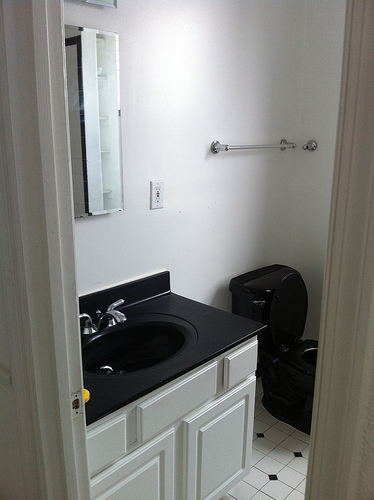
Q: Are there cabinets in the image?
A: Yes, there is a cabinet.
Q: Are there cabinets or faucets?
A: Yes, there is a cabinet.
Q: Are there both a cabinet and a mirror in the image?
A: Yes, there are both a cabinet and a mirror.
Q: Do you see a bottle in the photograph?
A: No, there are no bottles.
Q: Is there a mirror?
A: Yes, there is a mirror.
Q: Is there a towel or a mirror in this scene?
A: Yes, there is a mirror.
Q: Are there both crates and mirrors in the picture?
A: No, there is a mirror but no crates.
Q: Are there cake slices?
A: No, there are no cake slices.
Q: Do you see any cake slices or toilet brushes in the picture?
A: No, there are no cake slices or toilet brushes.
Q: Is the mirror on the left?
A: Yes, the mirror is on the left of the image.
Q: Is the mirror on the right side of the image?
A: No, the mirror is on the left of the image.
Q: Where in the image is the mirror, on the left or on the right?
A: The mirror is on the left of the image.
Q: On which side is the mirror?
A: The mirror is on the left of the image.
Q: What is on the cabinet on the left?
A: The mirror is on the cabinet.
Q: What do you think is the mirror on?
A: The mirror is on the cabinet.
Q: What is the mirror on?
A: The mirror is on the cabinet.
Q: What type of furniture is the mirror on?
A: The mirror is on the cabinet.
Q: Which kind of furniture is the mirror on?
A: The mirror is on the cabinet.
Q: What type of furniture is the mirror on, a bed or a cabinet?
A: The mirror is on a cabinet.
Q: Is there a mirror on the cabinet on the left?
A: Yes, there is a mirror on the cabinet.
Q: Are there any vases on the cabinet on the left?
A: No, there is a mirror on the cabinet.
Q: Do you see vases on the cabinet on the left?
A: No, there is a mirror on the cabinet.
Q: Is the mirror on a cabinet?
A: Yes, the mirror is on a cabinet.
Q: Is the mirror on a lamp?
A: No, the mirror is on a cabinet.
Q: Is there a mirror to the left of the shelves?
A: Yes, there is a mirror to the left of the shelves.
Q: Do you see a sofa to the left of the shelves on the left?
A: No, there is a mirror to the left of the shelves.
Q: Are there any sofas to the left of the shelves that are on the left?
A: No, there is a mirror to the left of the shelves.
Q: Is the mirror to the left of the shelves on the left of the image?
A: Yes, the mirror is to the left of the shelves.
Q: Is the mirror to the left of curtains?
A: No, the mirror is to the left of the shelves.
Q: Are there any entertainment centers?
A: No, there are no entertainment centers.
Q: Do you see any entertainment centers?
A: No, there are no entertainment centers.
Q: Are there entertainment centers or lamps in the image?
A: No, there are no entertainment centers or lamps.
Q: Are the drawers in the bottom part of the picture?
A: Yes, the drawers are in the bottom of the image.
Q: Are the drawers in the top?
A: No, the drawers are in the bottom of the image.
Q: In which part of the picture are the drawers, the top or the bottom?
A: The drawers are in the bottom of the image.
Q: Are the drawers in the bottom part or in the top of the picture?
A: The drawers are in the bottom of the image.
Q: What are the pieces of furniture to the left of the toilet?
A: The pieces of furniture are drawers.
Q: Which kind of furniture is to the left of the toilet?
A: The pieces of furniture are drawers.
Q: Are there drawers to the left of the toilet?
A: Yes, there are drawers to the left of the toilet.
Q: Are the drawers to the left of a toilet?
A: Yes, the drawers are to the left of a toilet.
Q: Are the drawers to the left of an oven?
A: No, the drawers are to the left of a toilet.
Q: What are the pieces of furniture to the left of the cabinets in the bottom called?
A: The pieces of furniture are drawers.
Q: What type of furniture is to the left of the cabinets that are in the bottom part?
A: The pieces of furniture are drawers.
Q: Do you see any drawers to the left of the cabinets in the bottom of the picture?
A: Yes, there are drawers to the left of the cabinets.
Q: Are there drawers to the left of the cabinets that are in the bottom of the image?
A: Yes, there are drawers to the left of the cabinets.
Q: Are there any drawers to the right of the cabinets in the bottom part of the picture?
A: No, the drawers are to the left of the cabinets.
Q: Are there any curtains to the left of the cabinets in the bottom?
A: No, there are drawers to the left of the cabinets.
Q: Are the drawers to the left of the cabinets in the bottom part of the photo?
A: Yes, the drawers are to the left of the cabinets.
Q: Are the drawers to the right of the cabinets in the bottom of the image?
A: No, the drawers are to the left of the cabinets.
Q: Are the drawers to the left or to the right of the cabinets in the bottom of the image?
A: The drawers are to the left of the cabinets.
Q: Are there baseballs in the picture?
A: No, there are no baseballs.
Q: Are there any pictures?
A: No, there are no pictures.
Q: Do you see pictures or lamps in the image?
A: No, there are no pictures or lamps.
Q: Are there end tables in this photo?
A: No, there are no end tables.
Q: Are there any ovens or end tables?
A: No, there are no end tables or ovens.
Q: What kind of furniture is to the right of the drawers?
A: The pieces of furniture are cabinets.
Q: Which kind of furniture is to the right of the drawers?
A: The pieces of furniture are cabinets.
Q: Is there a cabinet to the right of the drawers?
A: Yes, there are cabinets to the right of the drawers.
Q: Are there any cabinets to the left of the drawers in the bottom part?
A: No, the cabinets are to the right of the drawers.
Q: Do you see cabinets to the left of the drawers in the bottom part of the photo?
A: No, the cabinets are to the right of the drawers.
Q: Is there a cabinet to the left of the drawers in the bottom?
A: No, the cabinets are to the right of the drawers.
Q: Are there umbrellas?
A: No, there are no umbrellas.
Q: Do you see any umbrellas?
A: No, there are no umbrellas.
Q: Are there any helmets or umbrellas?
A: No, there are no umbrellas or helmets.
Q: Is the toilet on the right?
A: Yes, the toilet is on the right of the image.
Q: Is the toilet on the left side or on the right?
A: The toilet is on the right of the image.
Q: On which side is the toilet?
A: The toilet is on the right of the image.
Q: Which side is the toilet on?
A: The toilet is on the right of the image.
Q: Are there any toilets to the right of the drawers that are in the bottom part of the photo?
A: Yes, there is a toilet to the right of the drawers.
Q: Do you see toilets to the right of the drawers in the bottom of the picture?
A: Yes, there is a toilet to the right of the drawers.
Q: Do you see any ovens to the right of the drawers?
A: No, there is a toilet to the right of the drawers.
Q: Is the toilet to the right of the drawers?
A: Yes, the toilet is to the right of the drawers.